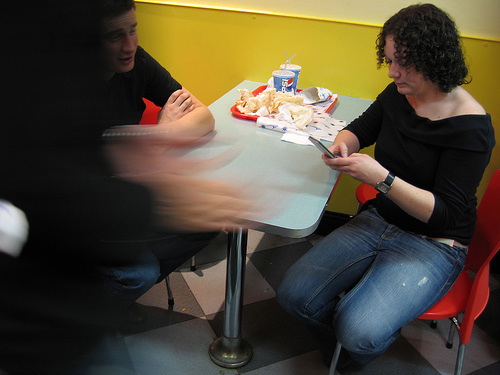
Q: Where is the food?
A: On the tray.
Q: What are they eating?
A: Tacos.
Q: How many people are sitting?
A: Two.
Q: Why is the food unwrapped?
A: It has been eaten.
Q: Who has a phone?
A: The woman sitting.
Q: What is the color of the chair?
A: Red.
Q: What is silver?
A: The table leg.